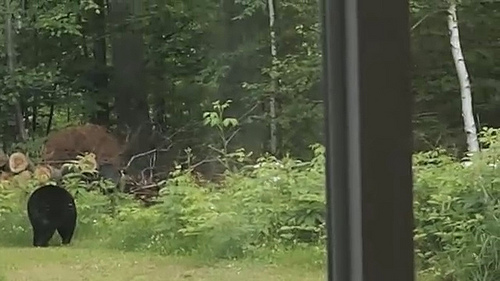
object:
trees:
[447, 0, 484, 165]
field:
[0, 237, 468, 280]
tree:
[81, 0, 113, 126]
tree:
[102, 0, 160, 179]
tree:
[45, 0, 66, 136]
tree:
[0, 1, 34, 146]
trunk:
[265, 0, 281, 158]